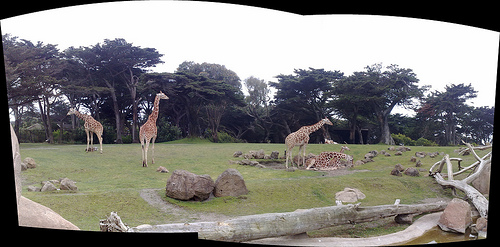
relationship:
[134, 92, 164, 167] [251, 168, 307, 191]
giraffe in field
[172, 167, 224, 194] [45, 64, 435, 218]
rock in field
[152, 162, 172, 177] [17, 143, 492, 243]
rock in field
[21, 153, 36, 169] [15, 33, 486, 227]
rock in field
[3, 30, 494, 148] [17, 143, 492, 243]
trees in field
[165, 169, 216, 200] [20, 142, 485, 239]
rock in green field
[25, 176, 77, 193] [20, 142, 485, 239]
rocks in green field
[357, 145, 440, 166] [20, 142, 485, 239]
rocks in green field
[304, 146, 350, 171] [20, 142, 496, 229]
giraffe laying in green field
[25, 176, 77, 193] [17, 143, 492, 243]
rocks in field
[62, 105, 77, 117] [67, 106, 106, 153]
head of giraffe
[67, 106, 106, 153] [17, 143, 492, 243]
giraffe in field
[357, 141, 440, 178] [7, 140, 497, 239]
rocks on ground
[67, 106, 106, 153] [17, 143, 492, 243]
giraffe in a field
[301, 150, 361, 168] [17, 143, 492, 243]
giraffe in a field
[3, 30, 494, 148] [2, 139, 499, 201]
trees in field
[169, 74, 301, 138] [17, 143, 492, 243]
tree lying on field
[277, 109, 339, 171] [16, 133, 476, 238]
giraffe in a field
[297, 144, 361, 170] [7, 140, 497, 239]
giraffe lying down on ground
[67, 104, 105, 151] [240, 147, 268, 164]
giraffe in a green  with rock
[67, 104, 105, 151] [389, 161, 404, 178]
giraffe in a green  with rock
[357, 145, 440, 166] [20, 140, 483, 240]
rocks laying on grass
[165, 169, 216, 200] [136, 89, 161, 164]
rock in park with giraffe